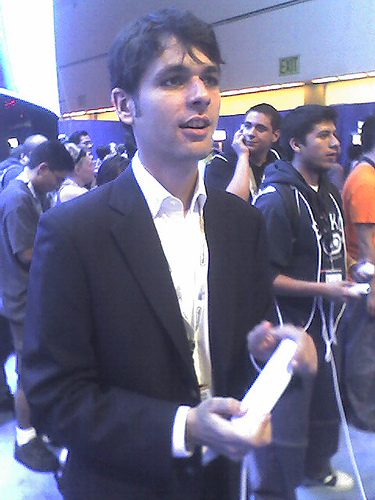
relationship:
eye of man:
[161, 76, 184, 86] [29, 6, 314, 497]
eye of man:
[199, 73, 223, 85] [29, 6, 314, 497]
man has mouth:
[255, 103, 371, 493] [178, 113, 214, 136]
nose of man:
[186, 77, 211, 108] [255, 103, 371, 493]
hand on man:
[180, 394, 278, 461] [29, 6, 314, 497]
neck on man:
[132, 159, 201, 193] [7, 1, 327, 498]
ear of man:
[110, 83, 137, 128] [29, 6, 314, 497]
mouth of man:
[179, 113, 210, 136] [29, 6, 314, 497]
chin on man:
[178, 129, 217, 169] [29, 6, 314, 497]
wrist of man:
[185, 411, 195, 447] [29, 6, 314, 497]